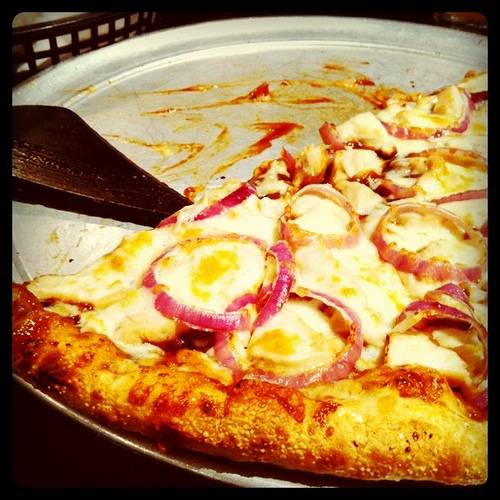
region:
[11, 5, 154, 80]
a brown plastic basket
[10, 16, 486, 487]
a metal pizza tray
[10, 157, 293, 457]
a slice of pizza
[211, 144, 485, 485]
a slice of pizza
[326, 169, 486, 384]
a slice of pizza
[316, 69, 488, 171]
a slice of pizza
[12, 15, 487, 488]
metal tray under the pizza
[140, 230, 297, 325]
red onion on top of the pizza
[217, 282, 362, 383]
red onion overlapping red onion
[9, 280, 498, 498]
the crust is golden brown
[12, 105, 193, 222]
spatula on top of the tray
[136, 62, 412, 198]
tomato sauce smeared on top of the tray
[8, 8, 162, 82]
brown plastic basket behind the tray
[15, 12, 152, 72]
white napkin inside the basket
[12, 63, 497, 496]
the pizza is on top of the tray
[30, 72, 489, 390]
the cheese is white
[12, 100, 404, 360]
pizza in a pan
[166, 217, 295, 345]
onions on top of a pizza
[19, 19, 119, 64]
basket next to pizza pan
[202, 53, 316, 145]
tomato sauce on the pan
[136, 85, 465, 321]
four slices of pizza on the pan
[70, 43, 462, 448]
cheese pizza on the pan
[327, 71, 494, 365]
cheese pizza on the pan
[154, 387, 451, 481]
the crust is brown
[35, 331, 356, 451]
dark brown spots on crust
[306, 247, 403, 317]
the cheese is white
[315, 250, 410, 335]
the cheese is melted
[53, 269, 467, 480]
crust on the pizza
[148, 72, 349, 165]
sauce on the tray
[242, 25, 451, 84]
the tray is silver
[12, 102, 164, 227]
the spatula is dark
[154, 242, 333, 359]
the onions are red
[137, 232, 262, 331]
red onion slice on pizza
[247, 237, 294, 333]
red onion slice on pizza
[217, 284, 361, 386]
red onion slice on pizza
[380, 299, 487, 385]
red onion slice on pizza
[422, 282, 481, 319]
red onion slice on pizza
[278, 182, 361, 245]
red onion slice on pizza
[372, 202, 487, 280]
red onion slice on pizza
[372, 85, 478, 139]
red onion slice on pizza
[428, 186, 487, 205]
red onion slice on pizza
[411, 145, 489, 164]
red onion slice on pizza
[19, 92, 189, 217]
the pizza server is on the pan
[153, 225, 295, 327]
the sliced onion is purple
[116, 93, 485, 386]
the cheese on pizza is white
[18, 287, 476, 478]
the crust of the pizza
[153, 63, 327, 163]
pizza sauce is on the metal pan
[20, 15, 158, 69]
a basket with square holes on the side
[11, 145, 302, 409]
a slice of pizza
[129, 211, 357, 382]
onion slices on a pizza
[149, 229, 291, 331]
Red onion ring in cheese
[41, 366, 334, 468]
corn meal on pizza crust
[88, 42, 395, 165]
sauce and cheese left on the pizza pan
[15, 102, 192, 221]
a overturned pizza server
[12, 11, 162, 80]
brown plastic basket with white paper inside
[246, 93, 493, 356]
onions and melted mozzarella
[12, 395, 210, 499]
dark wood table top